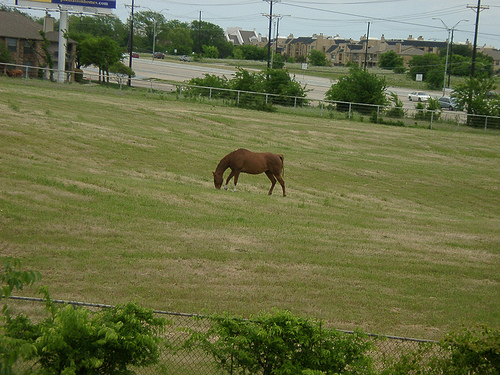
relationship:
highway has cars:
[79, 52, 494, 124] [409, 90, 433, 103]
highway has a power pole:
[79, 52, 494, 124] [266, 1, 272, 82]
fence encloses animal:
[0, 62, 499, 134] [210, 148, 286, 196]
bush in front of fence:
[325, 65, 389, 115] [0, 62, 499, 134]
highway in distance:
[79, 52, 494, 124] [126, 50, 496, 117]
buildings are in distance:
[2, 9, 78, 84] [126, 50, 496, 117]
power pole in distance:
[263, 1, 276, 81] [126, 50, 496, 117]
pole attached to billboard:
[58, 13, 67, 84] [15, 1, 118, 17]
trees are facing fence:
[70, 36, 136, 82] [0, 62, 499, 134]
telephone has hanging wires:
[129, 3, 136, 73] [140, 5, 274, 19]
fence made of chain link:
[0, 62, 499, 134] [91, 76, 119, 91]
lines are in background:
[129, 3, 272, 13] [51, 8, 500, 114]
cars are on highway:
[409, 90, 433, 103] [79, 52, 494, 124]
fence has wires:
[0, 62, 499, 134] [187, 86, 211, 102]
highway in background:
[79, 52, 494, 124] [51, 8, 500, 114]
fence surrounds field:
[0, 62, 499, 134] [0, 73, 499, 375]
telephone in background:
[129, 3, 136, 73] [51, 8, 500, 114]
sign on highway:
[13, 0, 117, 19] [79, 52, 494, 124]